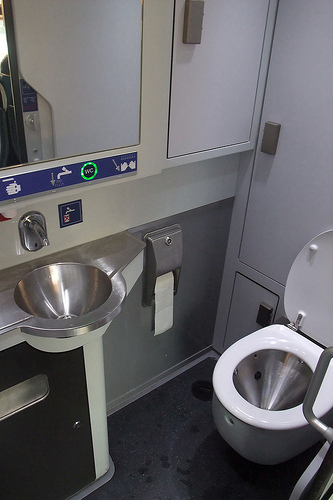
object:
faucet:
[19, 209, 51, 252]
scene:
[0, 0, 333, 500]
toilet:
[209, 226, 333, 467]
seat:
[211, 323, 332, 428]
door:
[0, 339, 117, 495]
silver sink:
[12, 260, 112, 338]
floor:
[84, 355, 309, 497]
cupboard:
[210, 2, 332, 357]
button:
[80, 162, 98, 182]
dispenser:
[143, 221, 183, 306]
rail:
[302, 346, 332, 449]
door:
[164, 0, 279, 155]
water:
[137, 465, 149, 475]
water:
[190, 422, 201, 434]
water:
[178, 477, 191, 487]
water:
[160, 456, 169, 468]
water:
[146, 476, 152, 483]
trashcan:
[0, 337, 114, 497]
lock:
[74, 420, 81, 429]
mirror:
[3, 0, 140, 172]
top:
[213, 324, 333, 429]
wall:
[2, 0, 183, 185]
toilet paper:
[154, 270, 174, 336]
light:
[80, 161, 98, 182]